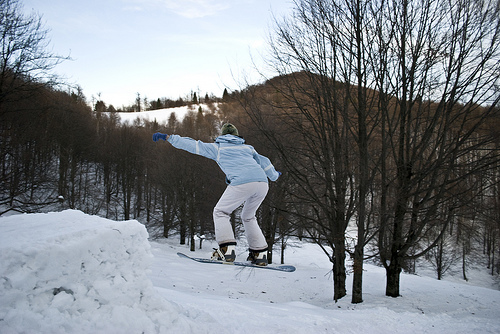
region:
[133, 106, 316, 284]
person snowboarding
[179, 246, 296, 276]
blue snowboard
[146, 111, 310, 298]
person mid snowboard jump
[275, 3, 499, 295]
tall, dark trees with no leaves on the branches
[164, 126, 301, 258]
light blue winter jacket with white snow pants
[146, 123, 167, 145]
tiny royal blue glove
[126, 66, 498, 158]
hill with a little bit of snow on it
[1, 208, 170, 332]
mound of white snow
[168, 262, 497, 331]
white snow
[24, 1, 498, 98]
baby blue sky with a few clouds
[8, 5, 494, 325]
a skier in the forest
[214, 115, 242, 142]
a green ski cap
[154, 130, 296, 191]
a blue ski coat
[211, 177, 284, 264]
a pair of white ski pants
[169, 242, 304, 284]
a blue snowboard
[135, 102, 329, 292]
a snowboarder jumps a hill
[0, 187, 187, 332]
a huge pile of snow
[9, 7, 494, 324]
a snowboarder doing a trick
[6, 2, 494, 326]
a person snowboarding in the forest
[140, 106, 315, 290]
snowboarder in the air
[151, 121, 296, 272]
a woman on a snowboard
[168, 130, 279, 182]
a light blue jacket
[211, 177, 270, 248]
a pair of white snow pants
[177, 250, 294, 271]
a dark snowboard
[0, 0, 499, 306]
trees in front of the snowboarder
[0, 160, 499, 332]
snow on the ground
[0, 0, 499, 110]
a blue sky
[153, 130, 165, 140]
a blue ski glove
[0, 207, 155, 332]
a large pile of snow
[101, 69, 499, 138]
a hill in the background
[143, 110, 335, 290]
In the air on a snowboard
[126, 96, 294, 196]
Wearing a light blue ski jacket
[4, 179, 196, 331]
Mound of snow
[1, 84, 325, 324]
Jumping off a pile of snow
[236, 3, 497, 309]
No leaves on the trees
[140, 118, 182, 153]
Dark blue gloves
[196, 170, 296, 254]
Sporting white ski pants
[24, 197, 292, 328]
Hard packed snow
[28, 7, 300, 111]
Clear skies above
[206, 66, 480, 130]
A hill in the distance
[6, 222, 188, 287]
The snow is white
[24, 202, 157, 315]
The snow is white